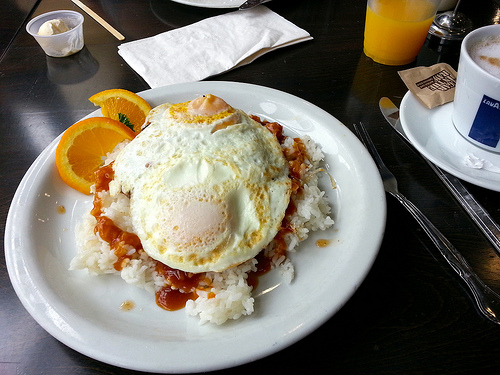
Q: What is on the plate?
A: Breakfast.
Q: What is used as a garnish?
A: An orange.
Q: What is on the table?
A: White napkin.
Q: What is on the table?
A: A knife and fork.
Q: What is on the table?
A: A silver fork.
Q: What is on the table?
A: A saucer.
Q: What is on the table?
A: A napkin.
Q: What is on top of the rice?
A: Eggs.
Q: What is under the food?
A: A white plate.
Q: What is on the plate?
A: Food.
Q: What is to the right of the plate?
A: A fork.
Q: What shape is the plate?
A: Round.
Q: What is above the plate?
A: Paper napkins.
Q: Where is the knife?
A: Beside the fork.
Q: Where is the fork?
A: To the right of the plate.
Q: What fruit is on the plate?
A: Orange slices.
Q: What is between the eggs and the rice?
A: Red sauce.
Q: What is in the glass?
A: Orange Juice.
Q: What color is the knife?
A: Silver.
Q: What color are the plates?
A: White.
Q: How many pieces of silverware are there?
A: Two.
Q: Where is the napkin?
A: Above the plate.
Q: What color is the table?
A: Black.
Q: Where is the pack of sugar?
A: Beside coffee cup.